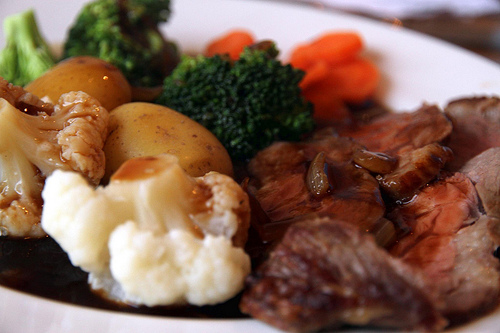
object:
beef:
[254, 214, 452, 330]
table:
[423, 7, 499, 43]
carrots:
[201, 26, 263, 70]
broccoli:
[0, 8, 60, 89]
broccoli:
[60, 1, 180, 91]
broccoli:
[164, 36, 311, 159]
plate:
[1, 1, 496, 329]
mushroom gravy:
[116, 151, 171, 185]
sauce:
[4, 235, 181, 308]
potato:
[17, 51, 128, 117]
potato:
[102, 98, 234, 185]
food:
[6, 1, 495, 331]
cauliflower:
[37, 149, 256, 313]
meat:
[253, 133, 385, 251]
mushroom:
[350, 144, 397, 176]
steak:
[342, 100, 465, 202]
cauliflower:
[0, 89, 109, 240]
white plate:
[2, 0, 493, 330]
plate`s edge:
[175, 0, 499, 68]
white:
[164, 0, 498, 112]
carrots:
[283, 25, 381, 129]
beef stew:
[0, 77, 499, 331]